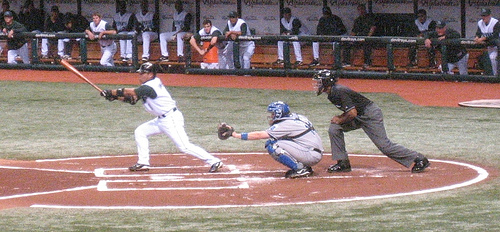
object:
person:
[407, 9, 436, 67]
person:
[343, 4, 386, 68]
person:
[311, 6, 346, 64]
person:
[274, 6, 304, 66]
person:
[159, 0, 192, 58]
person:
[130, 0, 159, 62]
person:
[36, 5, 67, 58]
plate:
[151, 173, 184, 180]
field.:
[0, 84, 497, 231]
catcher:
[221, 101, 323, 179]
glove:
[218, 124, 234, 140]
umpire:
[313, 69, 431, 175]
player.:
[99, 61, 226, 172]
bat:
[59, 60, 114, 97]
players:
[0, 11, 32, 64]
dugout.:
[0, 0, 499, 77]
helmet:
[312, 68, 342, 92]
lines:
[0, 151, 489, 210]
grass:
[1, 81, 497, 232]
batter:
[101, 62, 223, 172]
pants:
[132, 109, 222, 165]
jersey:
[142, 78, 177, 120]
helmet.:
[138, 62, 158, 71]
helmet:
[135, 62, 158, 73]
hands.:
[101, 87, 119, 97]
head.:
[135, 62, 157, 84]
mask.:
[266, 101, 291, 124]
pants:
[328, 106, 417, 168]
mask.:
[313, 70, 335, 96]